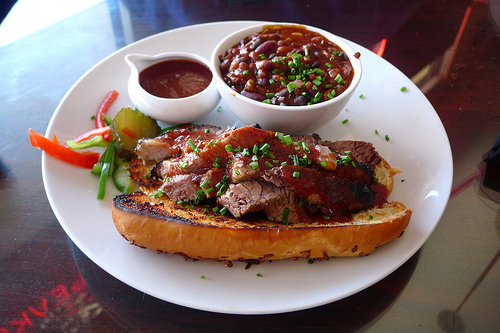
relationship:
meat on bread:
[147, 133, 352, 217] [122, 199, 386, 267]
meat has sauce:
[147, 133, 352, 217] [266, 151, 329, 200]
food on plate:
[117, 35, 380, 256] [49, 9, 448, 321]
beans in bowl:
[238, 35, 301, 91] [255, 94, 346, 136]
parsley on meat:
[229, 141, 284, 173] [147, 133, 352, 217]